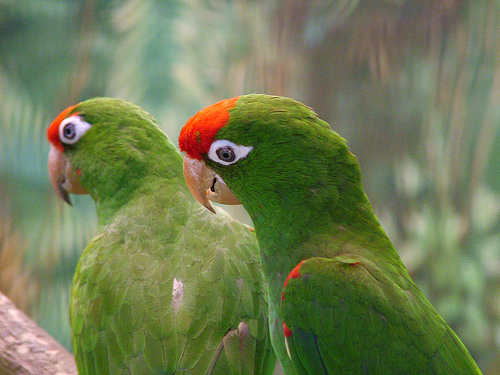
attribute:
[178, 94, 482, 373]
bird — sitting, green, resting, perched, light green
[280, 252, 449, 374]
wing — green, red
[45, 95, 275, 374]
bird — red, green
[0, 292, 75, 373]
branch — brown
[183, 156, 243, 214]
beak — yellow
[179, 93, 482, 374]
feathers — green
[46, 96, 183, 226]
head — green, red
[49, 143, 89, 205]
beak — closed